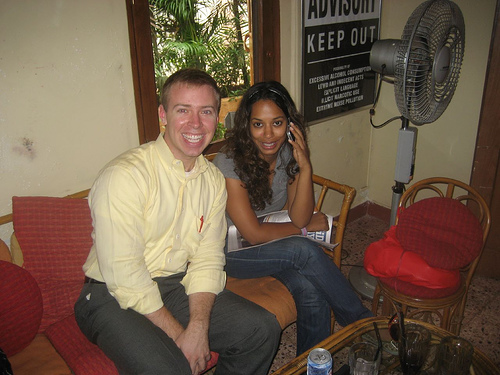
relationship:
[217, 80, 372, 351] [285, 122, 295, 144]
woman on cell phone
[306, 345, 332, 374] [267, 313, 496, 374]
can on table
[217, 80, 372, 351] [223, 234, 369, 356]
woman wearing pants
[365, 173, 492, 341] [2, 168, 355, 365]
chair by bench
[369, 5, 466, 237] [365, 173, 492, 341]
fan near chair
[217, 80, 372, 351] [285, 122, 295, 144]
woman using a cell phone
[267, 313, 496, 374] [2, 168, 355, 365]
table near bench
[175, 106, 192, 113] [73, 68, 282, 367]
eye of man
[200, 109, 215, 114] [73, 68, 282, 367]
eye of man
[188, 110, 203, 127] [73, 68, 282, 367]
nose of man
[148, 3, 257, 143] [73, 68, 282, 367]
window behind man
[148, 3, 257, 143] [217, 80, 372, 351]
window behind woman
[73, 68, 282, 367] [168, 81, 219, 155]
man has a face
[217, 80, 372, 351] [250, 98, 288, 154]
woman has a face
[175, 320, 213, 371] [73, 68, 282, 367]
hand of man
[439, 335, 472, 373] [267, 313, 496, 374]
bottle on table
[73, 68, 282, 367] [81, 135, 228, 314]
man wearing shirt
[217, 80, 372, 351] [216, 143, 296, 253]
woman wearing shirt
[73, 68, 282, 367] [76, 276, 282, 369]
man wearing pants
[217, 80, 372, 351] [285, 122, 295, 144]
woman holding cell phone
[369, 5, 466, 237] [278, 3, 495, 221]
fan in corner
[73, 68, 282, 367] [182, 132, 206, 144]
man showing teeth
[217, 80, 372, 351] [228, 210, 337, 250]
woman holding newspaper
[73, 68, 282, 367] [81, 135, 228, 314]
man wears shirt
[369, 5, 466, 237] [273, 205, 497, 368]
fan on floor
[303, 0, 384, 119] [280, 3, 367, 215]
sign on wall